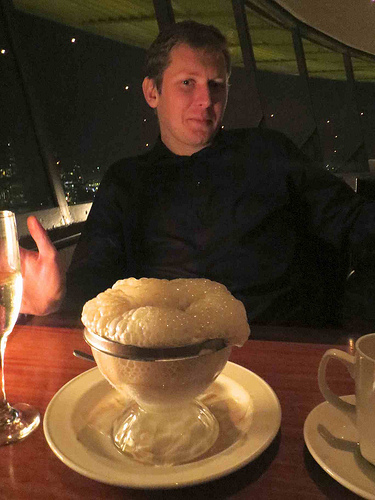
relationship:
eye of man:
[181, 77, 197, 88] [61, 16, 373, 327]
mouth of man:
[187, 114, 216, 128] [61, 16, 373, 327]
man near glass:
[61, 16, 373, 327] [0, 209, 44, 446]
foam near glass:
[75, 274, 250, 357] [0, 209, 44, 446]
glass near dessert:
[0, 209, 44, 446] [76, 270, 252, 466]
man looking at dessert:
[61, 16, 373, 327] [76, 270, 252, 466]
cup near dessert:
[314, 332, 374, 463] [76, 270, 252, 466]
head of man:
[138, 17, 236, 150] [61, 16, 373, 327]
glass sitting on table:
[0, 209, 44, 446] [2, 307, 371, 496]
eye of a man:
[181, 77, 197, 88] [61, 16, 373, 327]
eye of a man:
[205, 79, 223, 93] [61, 16, 373, 327]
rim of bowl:
[84, 317, 253, 362] [77, 327, 240, 462]